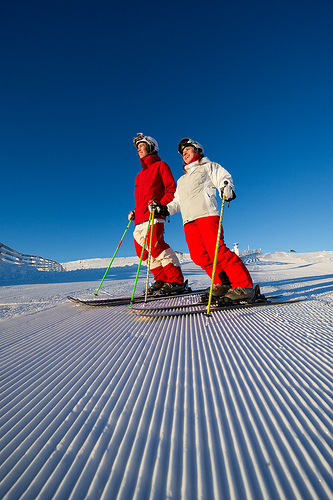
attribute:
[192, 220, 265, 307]
pants — red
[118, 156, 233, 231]
jacket — white, red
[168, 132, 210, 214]
girl — smiling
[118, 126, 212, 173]
helmet — white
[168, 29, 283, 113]
sky — clear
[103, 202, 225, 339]
ski poles — yellow, green